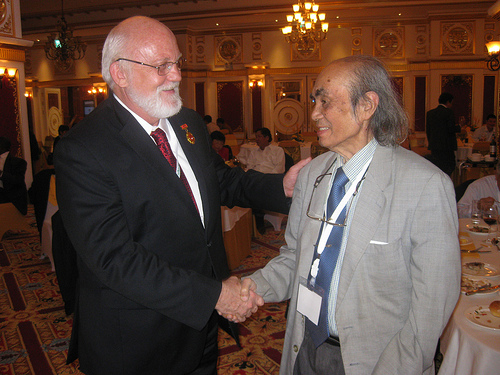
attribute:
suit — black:
[54, 88, 292, 373]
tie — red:
[150, 127, 196, 208]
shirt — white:
[243, 142, 285, 172]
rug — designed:
[10, 222, 285, 373]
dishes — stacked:
[461, 137, 492, 169]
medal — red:
[177, 121, 197, 148]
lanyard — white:
[306, 161, 370, 288]